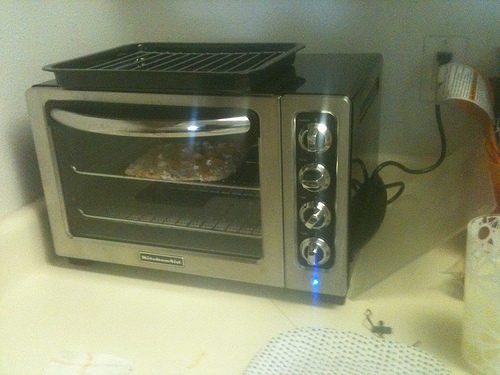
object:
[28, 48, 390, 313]
oven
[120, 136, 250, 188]
pizza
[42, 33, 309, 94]
tray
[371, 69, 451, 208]
cord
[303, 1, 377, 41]
wall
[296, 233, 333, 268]
knobs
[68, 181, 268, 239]
racks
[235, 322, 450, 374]
pot holder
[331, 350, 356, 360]
dots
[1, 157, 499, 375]
counter top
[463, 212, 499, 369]
glass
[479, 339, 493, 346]
liquid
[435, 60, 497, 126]
tag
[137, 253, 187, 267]
logo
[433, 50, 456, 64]
plug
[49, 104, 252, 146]
handle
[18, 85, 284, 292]
door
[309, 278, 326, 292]
light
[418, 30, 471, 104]
outlet